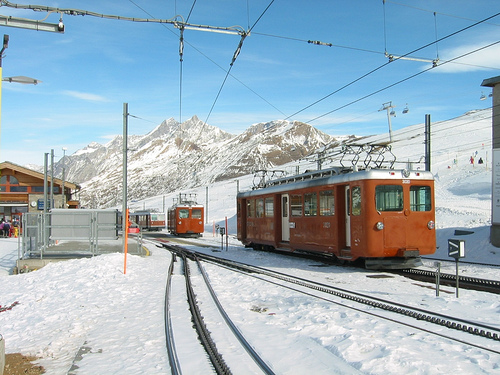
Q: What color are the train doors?
A: White.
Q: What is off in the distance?
A: Mountains.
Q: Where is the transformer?
A: Inside the chain link fence.